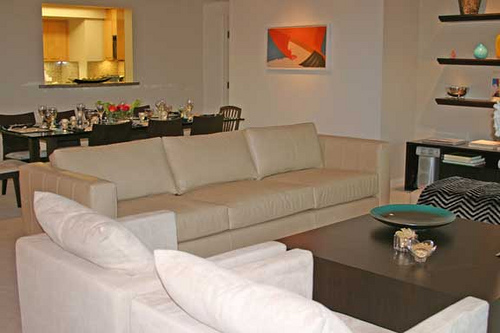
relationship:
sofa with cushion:
[18, 121, 395, 259] [263, 158, 380, 217]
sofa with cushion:
[18, 121, 395, 259] [174, 160, 314, 237]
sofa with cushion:
[18, 121, 395, 259] [99, 177, 232, 251]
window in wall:
[38, 1, 140, 86] [1, 2, 224, 125]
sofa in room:
[25, 102, 400, 270] [4, 3, 483, 321]